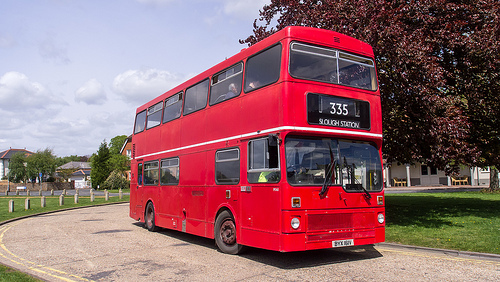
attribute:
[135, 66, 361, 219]
bus — tall, red, large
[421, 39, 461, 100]
tree — brown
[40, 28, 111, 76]
sky — blue, gray